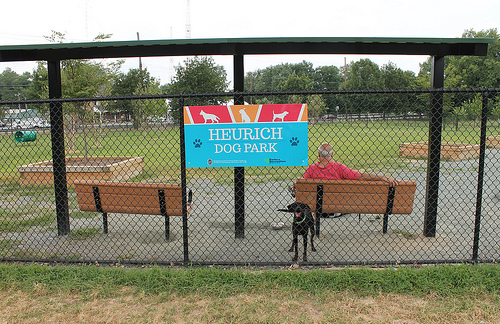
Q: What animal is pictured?
A: Dog.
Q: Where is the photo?
A: Dog park.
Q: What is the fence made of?
A: Metal.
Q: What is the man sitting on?
A: Bench.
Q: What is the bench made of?
A: Wood.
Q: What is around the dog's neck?
A: Collar.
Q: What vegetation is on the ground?
A: Grass.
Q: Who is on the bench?
A: A man.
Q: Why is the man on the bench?
A: To watch a dog.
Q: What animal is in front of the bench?
A: A dog.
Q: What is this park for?
A: Dogs.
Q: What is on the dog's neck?
A: A collar.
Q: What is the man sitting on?
A: A bench.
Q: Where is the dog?
A: At a dog park.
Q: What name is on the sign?
A: Heurich.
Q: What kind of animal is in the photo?
A: A dog.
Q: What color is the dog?
A: Black.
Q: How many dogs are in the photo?
A: One.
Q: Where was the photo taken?
A: Heurich Dog Park.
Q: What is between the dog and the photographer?
A: A fence.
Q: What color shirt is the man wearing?
A: Red.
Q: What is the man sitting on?
A: A bench.